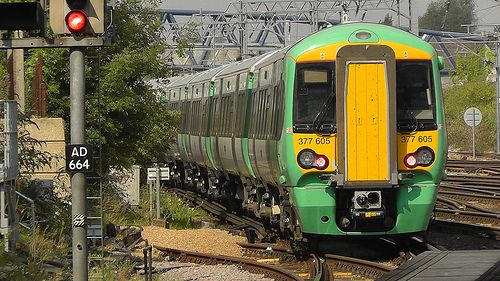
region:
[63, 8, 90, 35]
A red circular light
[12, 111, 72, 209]
A cement support structure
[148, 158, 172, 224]
Back side of a rectangular sign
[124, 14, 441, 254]
A train driving on the tracks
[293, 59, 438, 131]
Windshield on a train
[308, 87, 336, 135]
Windshield wiper on a train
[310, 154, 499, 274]
Many sets of train tracks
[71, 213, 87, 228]
A black and white striped sign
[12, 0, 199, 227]
A tree growing beside the train tracks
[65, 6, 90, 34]
A light light up red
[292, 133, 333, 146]
377605 on the left side of the train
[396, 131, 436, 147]
377605 on the right side of the train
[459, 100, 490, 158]
some type of sign facing away from view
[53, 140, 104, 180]
small black sign with AD 644 on it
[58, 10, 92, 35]
Red traffic light lit up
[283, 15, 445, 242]
Front of train colored yellow and green.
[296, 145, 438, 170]
head lights on front of train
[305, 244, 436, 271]
Railroad tracks in front of train.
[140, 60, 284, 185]
Train cars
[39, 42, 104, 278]
metal pole that holds traffic light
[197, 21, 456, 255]
Green and yellow train on tracks.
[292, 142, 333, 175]
Headlight in front of train.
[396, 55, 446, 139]
Front left window of train.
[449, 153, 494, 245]
Numerous train tracks next to train.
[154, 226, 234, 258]
Gravel next to train track.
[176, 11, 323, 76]
Steel girders on bridge.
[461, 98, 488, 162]
A sign next to train tracks.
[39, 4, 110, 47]
Traffic light on red.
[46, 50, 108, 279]
Post traffic light mounted on.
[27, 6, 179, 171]
Tree growing to train tracks.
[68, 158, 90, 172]
The numbers 664 written in white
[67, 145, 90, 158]
The letters AD written in white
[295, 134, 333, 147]
The numbers 377 605 written in black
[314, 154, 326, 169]
An illuminated head light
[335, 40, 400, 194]
A yellow door outlined in silver metal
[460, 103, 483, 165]
The back of a circular sign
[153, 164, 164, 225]
Metal pole holding a sign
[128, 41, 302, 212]
Train cars behind the engine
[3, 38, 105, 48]
Circular rivets on metal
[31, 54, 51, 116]
A brown rusted piece of metal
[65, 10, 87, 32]
A red traffic light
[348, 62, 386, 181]
A yellow train door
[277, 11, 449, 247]
A green and yellow front of a train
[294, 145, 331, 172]
A train's head light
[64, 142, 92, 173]
A black sign with white writing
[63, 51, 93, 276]
A grey pole for a traffic light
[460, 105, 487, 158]
The back side of a sign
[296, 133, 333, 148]
Black numbers written on the train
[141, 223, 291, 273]
Gravel between the train tracks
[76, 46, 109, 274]
A ladder made out of metal